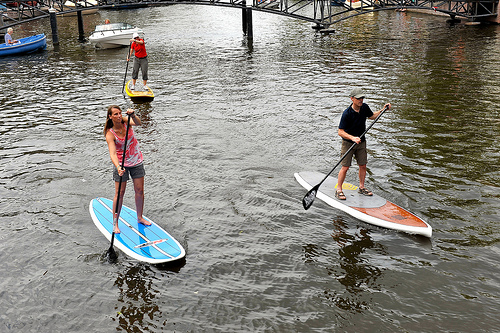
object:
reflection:
[110, 262, 163, 333]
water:
[0, 2, 499, 333]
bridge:
[0, 0, 499, 49]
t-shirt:
[338, 102, 374, 143]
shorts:
[340, 139, 368, 166]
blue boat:
[0, 33, 48, 56]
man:
[4, 27, 19, 46]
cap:
[350, 87, 365, 98]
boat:
[85, 22, 146, 50]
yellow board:
[125, 79, 155, 98]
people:
[126, 32, 148, 90]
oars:
[122, 41, 132, 93]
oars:
[302, 104, 389, 210]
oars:
[105, 111, 135, 259]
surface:
[187, 202, 343, 332]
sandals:
[335, 187, 374, 200]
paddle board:
[294, 170, 433, 239]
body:
[334, 88, 391, 201]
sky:
[201, 71, 263, 100]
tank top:
[109, 122, 143, 167]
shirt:
[108, 122, 143, 168]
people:
[103, 105, 152, 234]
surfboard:
[293, 170, 432, 237]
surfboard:
[89, 196, 186, 264]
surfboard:
[124, 79, 154, 98]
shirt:
[131, 38, 148, 58]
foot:
[335, 189, 346, 200]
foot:
[358, 186, 372, 195]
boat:
[88, 196, 186, 265]